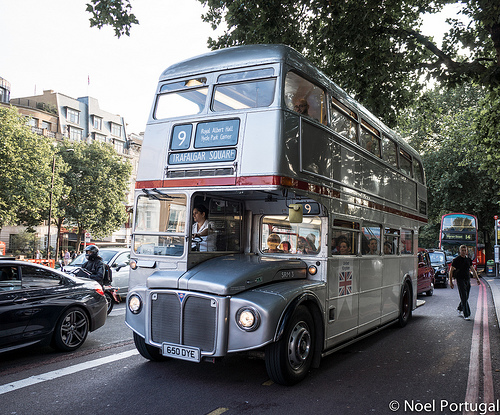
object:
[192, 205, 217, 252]
driver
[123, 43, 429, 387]
bus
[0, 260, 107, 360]
car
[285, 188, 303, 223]
mirror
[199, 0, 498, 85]
tree limb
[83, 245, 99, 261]
helmet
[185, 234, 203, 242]
wheel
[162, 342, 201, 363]
plate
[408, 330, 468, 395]
street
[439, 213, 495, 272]
bus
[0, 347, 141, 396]
line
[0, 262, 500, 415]
road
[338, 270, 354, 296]
flag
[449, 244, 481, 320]
man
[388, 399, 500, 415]
name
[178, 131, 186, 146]
number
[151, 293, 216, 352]
grill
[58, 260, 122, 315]
motorcycle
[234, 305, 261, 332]
headlight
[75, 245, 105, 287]
person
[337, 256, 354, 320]
sticker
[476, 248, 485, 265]
bus stop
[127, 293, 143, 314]
headlights